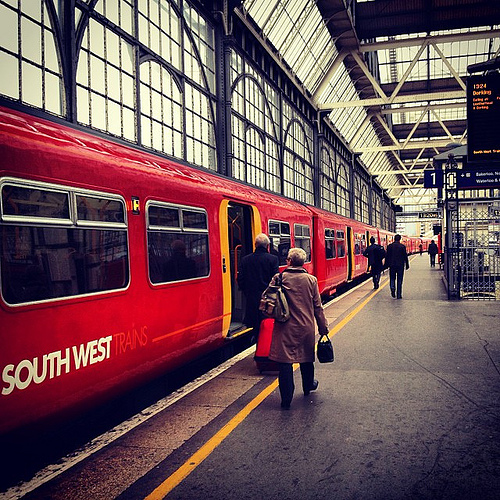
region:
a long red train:
[2, 66, 444, 451]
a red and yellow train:
[4, 76, 433, 446]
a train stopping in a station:
[4, 93, 428, 466]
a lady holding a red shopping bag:
[255, 244, 344, 421]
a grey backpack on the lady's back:
[257, 266, 290, 327]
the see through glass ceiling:
[356, 13, 497, 216]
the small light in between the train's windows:
[127, 188, 146, 225]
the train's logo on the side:
[1, 321, 153, 390]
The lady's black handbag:
[314, 329, 343, 374]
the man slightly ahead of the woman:
[235, 222, 283, 336]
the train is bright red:
[0, 106, 442, 429]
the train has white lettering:
[2, 333, 119, 398]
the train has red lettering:
[108, 326, 153, 358]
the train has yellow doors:
[216, 187, 263, 342]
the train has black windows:
[0, 173, 217, 313]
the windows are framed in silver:
[0, 174, 215, 309]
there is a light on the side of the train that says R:
[126, 193, 142, 213]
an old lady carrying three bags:
[252, 241, 334, 405]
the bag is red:
[252, 312, 283, 373]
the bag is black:
[315, 330, 341, 372]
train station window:
[64, 0, 231, 173]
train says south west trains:
[4, 317, 151, 402]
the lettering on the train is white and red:
[0, 316, 150, 400]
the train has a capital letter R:
[129, 195, 145, 214]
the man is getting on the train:
[230, 230, 282, 345]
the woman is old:
[255, 247, 338, 406]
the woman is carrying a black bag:
[315, 330, 335, 364]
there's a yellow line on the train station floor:
[140, 235, 430, 493]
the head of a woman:
[276, 241, 314, 273]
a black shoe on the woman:
[296, 372, 323, 398]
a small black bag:
[311, 327, 341, 368]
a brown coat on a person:
[257, 262, 330, 369]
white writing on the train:
[0, 329, 116, 394]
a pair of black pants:
[273, 358, 318, 400]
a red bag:
[251, 315, 278, 364]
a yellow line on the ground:
[141, 250, 421, 497]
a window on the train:
[141, 196, 216, 290]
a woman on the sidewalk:
[252, 241, 336, 417]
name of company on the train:
[1, 325, 151, 394]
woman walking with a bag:
[255, 245, 342, 410]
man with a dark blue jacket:
[234, 230, 281, 344]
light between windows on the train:
[131, 190, 143, 225]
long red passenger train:
[3, 102, 438, 434]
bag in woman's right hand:
[315, 326, 337, 368]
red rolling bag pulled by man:
[256, 309, 280, 377]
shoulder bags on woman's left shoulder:
[259, 272, 291, 323]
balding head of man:
[255, 232, 269, 249]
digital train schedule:
[464, 73, 499, 169]